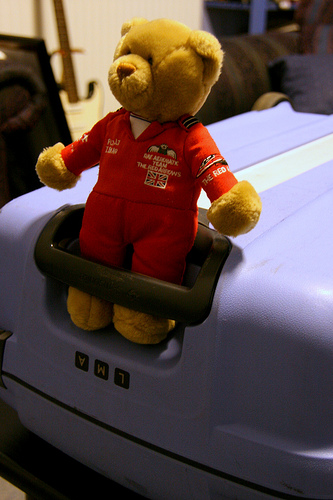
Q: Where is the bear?
A: On the suitcase.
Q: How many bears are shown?
A: One.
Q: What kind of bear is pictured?
A: A toy bear.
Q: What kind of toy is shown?
A: A stuffed animal.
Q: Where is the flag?
A: On the bear.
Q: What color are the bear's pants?
A: Red.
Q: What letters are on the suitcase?
A: LMA.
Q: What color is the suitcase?
A: Blue.